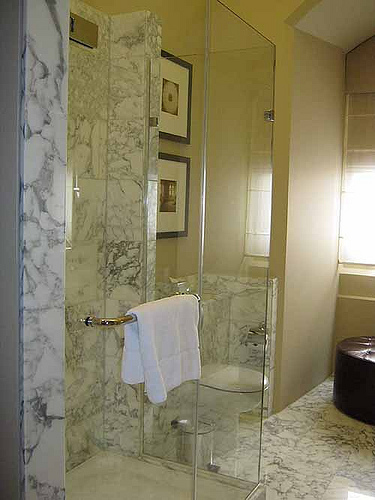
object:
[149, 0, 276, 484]
door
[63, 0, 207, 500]
shower door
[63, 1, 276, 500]
shower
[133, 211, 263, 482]
window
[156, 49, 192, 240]
art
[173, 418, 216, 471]
trash can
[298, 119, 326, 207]
ground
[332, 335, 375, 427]
seat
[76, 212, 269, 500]
glass shower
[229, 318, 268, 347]
holder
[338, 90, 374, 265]
window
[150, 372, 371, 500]
floor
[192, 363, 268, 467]
toilet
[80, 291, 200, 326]
bar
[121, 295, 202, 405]
bath towel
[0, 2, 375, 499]
bathroom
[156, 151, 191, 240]
picture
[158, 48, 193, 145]
picture